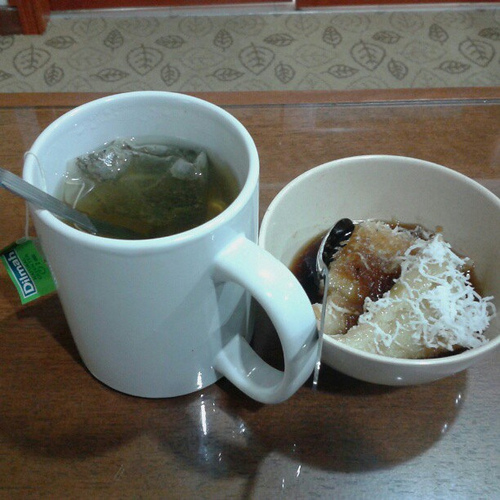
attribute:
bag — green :
[9, 227, 56, 299]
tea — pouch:
[83, 103, 227, 220]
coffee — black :
[295, 252, 326, 294]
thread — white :
[12, 152, 47, 242]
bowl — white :
[258, 147, 498, 379]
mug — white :
[0, 88, 317, 406]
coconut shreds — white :
[361, 236, 496, 354]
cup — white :
[22, 87, 319, 404]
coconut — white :
[366, 227, 496, 363]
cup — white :
[4, 80, 331, 405]